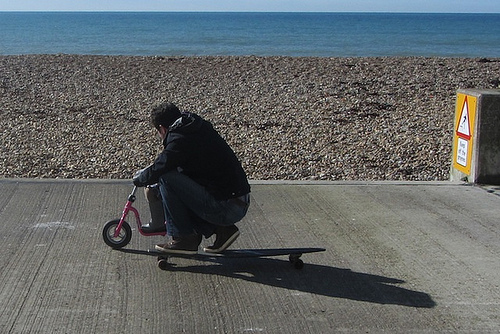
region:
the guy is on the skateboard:
[129, 84, 290, 267]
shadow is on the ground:
[255, 259, 443, 314]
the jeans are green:
[157, 186, 249, 238]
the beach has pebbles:
[243, 70, 425, 172]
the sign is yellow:
[439, 93, 488, 180]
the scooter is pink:
[98, 179, 170, 254]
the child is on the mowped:
[123, 178, 174, 239]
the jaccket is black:
[144, 123, 258, 198]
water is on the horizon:
[262, 37, 487, 60]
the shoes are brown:
[153, 223, 276, 253]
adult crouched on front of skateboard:
[126, 100, 251, 270]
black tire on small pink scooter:
[100, 172, 145, 247]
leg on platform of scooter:
[137, 182, 163, 232]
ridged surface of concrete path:
[16, 182, 481, 312]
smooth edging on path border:
[10, 175, 462, 192]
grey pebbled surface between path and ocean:
[30, 50, 441, 186]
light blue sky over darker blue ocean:
[90, 0, 415, 32]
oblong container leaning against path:
[450, 81, 496, 191]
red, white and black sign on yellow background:
[450, 75, 476, 172]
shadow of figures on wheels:
[163, 251, 435, 308]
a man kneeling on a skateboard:
[132, 101, 328, 269]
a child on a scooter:
[103, 163, 170, 248]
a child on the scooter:
[100, 179, 175, 264]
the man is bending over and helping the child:
[96, 99, 257, 264]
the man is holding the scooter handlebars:
[102, 155, 159, 207]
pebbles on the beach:
[0, 51, 497, 180]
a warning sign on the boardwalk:
[448, 93, 478, 175]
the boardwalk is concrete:
[0, 168, 497, 331]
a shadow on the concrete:
[176, 242, 441, 309]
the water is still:
[210, 22, 420, 52]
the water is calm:
[115, 17, 350, 46]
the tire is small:
[97, 215, 130, 248]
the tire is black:
[95, 213, 135, 253]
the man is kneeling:
[130, 84, 259, 255]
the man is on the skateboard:
[137, 100, 327, 280]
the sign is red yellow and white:
[445, 81, 485, 176]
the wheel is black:
[151, 254, 176, 275]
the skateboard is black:
[254, 225, 320, 264]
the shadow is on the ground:
[327, 239, 463, 322]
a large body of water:
[1, 10, 498, 55]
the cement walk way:
[3, 174, 498, 316]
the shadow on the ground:
[133, 254, 438, 308]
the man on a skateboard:
[148, 87, 330, 272]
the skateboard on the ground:
[138, 243, 328, 266]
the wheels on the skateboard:
[154, 253, 304, 270]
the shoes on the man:
[155, 227, 240, 253]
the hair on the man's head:
[149, 102, 178, 124]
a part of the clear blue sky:
[1, 1, 497, 11]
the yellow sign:
[450, 91, 474, 173]